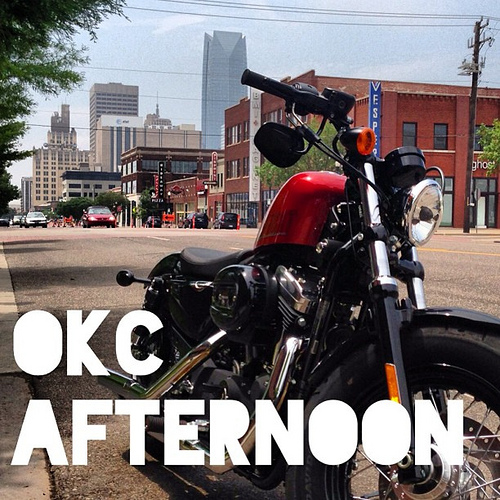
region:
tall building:
[201, 28, 248, 150]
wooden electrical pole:
[460, 18, 497, 230]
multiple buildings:
[20, 28, 495, 220]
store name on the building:
[471, 160, 496, 170]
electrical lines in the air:
[97, 0, 497, 36]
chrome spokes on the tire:
[327, 388, 497, 498]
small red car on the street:
[83, 205, 115, 227]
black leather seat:
[182, 246, 248, 272]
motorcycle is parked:
[120, 70, 492, 494]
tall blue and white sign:
[368, 80, 380, 157]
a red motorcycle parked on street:
[117, 64, 498, 499]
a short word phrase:
[1, 299, 468, 476]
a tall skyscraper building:
[189, 29, 269, 154]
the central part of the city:
[0, 79, 499, 231]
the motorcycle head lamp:
[390, 164, 450, 254]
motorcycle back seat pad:
[167, 229, 267, 279]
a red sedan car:
[80, 202, 117, 232]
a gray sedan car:
[21, 207, 47, 229]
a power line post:
[430, 7, 493, 236]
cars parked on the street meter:
[140, 207, 243, 229]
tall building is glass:
[201, 27, 247, 148]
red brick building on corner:
[350, 94, 497, 227]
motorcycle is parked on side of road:
[97, 66, 498, 499]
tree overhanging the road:
[0, 0, 128, 229]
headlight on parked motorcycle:
[403, 177, 443, 242]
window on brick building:
[401, 122, 415, 145]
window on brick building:
[434, 123, 447, 148]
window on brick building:
[472, 125, 481, 151]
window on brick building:
[141, 158, 162, 169]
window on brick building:
[171, 160, 194, 173]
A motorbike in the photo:
[167, 204, 418, 466]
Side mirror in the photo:
[247, 110, 319, 165]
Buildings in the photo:
[101, 78, 256, 181]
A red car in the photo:
[76, 201, 114, 226]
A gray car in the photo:
[22, 206, 48, 231]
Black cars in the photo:
[180, 208, 240, 233]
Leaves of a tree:
[475, 118, 496, 170]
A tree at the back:
[245, 105, 350, 180]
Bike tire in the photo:
[335, 330, 493, 428]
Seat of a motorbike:
[180, 239, 247, 271]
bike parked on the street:
[77, 55, 486, 497]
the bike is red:
[202, 136, 381, 286]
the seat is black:
[153, 217, 259, 279]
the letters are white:
[6, 273, 481, 486]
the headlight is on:
[374, 165, 461, 275]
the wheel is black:
[276, 310, 494, 491]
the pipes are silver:
[65, 313, 314, 453]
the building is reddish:
[310, 57, 489, 237]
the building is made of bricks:
[346, 62, 478, 238]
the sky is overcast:
[28, 10, 235, 140]